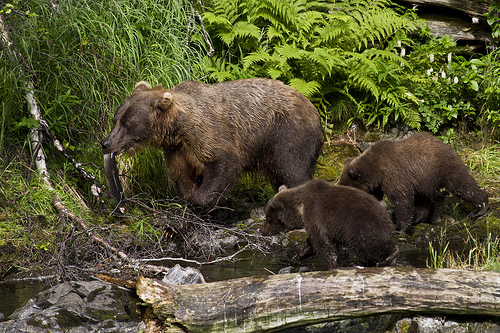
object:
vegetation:
[189, 0, 454, 147]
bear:
[257, 179, 397, 272]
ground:
[0, 110, 499, 332]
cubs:
[338, 131, 490, 234]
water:
[4, 278, 37, 303]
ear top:
[157, 91, 173, 110]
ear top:
[135, 81, 150, 90]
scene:
[0, 0, 500, 332]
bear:
[99, 77, 326, 213]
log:
[133, 266, 499, 332]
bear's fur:
[260, 94, 299, 136]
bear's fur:
[421, 147, 450, 170]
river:
[0, 240, 499, 324]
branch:
[5, 161, 304, 291]